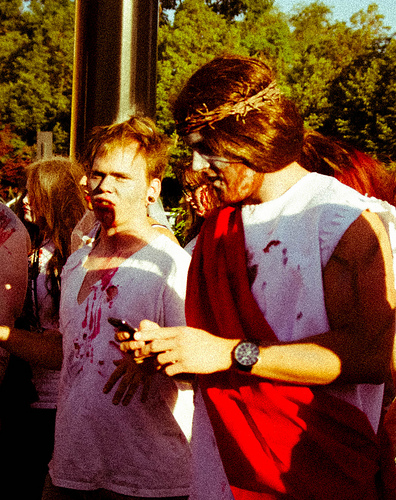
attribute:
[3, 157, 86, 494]
person — standing up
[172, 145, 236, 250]
person — standing up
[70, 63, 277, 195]
hair neat — thing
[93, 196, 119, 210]
mouth — slightly open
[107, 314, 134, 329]
phone — used, for calling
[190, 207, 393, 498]
sash — red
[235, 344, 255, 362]
face — clock's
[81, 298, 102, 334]
stains — red